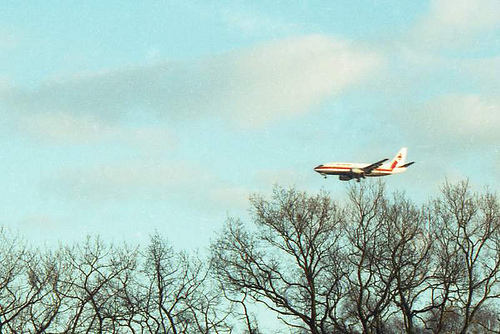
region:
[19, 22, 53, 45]
this is the sky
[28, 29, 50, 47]
the sky is blue in color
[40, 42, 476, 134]
these are some clouds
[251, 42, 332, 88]
the clouds are white in color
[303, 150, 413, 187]
this is an airplane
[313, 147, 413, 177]
the airplane is in the air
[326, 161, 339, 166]
the airplane is white in color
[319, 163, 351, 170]
this is a red strip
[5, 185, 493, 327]
these are some trees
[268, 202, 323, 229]
the tree has few leaves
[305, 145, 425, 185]
plane in the air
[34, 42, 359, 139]
large white cloud in the sky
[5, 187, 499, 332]
tree with no leaves on it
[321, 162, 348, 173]
red line on the plane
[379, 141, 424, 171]
red and white tail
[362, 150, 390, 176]
wing of the plane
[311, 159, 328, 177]
nose of the plane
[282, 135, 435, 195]
red and white plane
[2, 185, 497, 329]
brown tree tops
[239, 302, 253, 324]
skinny tree branch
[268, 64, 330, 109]
part of a cloud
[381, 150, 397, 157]
tip of a wing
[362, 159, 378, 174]
edge of a plane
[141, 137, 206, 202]
;part of the sky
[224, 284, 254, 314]
;part of a tree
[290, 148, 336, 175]
tip of a plane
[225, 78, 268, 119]
part of a cloud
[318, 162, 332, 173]
edge of a plane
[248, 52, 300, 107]
part of a cloud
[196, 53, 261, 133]
part of a cloud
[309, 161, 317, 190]
tip of a plane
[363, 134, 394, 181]
tip of a wing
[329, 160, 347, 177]
part of a plane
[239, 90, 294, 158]
part of a cloud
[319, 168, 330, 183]
part of a wheel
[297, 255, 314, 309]
part of a branch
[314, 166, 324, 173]
The tip of the nose of the plane.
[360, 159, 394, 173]
The side wing of the plane.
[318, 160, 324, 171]
The front window of the plane.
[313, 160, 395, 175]
The red stripe on the side of the plane.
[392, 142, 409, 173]
The tail of the plane.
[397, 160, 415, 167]
The side wing near the tail of the plane.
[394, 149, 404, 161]
The design on the tail of the plane.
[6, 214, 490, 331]
The trees beneath the plane.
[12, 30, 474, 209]
The white clouds in the sky.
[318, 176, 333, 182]
The front wheels of the plane.